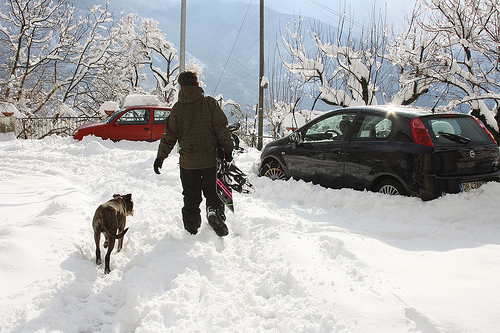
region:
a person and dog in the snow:
[33, 32, 373, 330]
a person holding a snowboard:
[129, 52, 281, 256]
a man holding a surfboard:
[122, 52, 259, 299]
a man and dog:
[51, 29, 301, 325]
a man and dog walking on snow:
[19, 35, 329, 327]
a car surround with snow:
[227, 62, 499, 263]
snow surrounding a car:
[211, 52, 499, 269]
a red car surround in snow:
[60, 50, 222, 177]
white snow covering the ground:
[224, 232, 404, 327]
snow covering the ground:
[266, 198, 467, 320]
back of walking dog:
[90, 196, 132, 261]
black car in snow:
[287, 105, 486, 217]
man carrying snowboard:
[161, 72, 243, 240]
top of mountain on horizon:
[280, 5, 318, 49]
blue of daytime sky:
[358, 3, 406, 28]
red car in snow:
[71, 97, 160, 159]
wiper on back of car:
[430, 121, 468, 154]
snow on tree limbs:
[330, 50, 423, 98]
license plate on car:
[450, 172, 490, 196]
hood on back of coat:
[171, 80, 213, 117]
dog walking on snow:
[93, 188, 133, 268]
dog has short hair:
[95, 191, 133, 267]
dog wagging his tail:
[93, 193, 133, 274]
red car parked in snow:
[71, 106, 173, 141]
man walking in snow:
[150, 71, 244, 240]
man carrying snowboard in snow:
[155, 71, 241, 236]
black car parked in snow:
[258, 107, 497, 193]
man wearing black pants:
[150, 74, 244, 237]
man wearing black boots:
[149, 71, 246, 236]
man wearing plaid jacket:
[148, 70, 243, 238]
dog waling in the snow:
[10, 194, 149, 264]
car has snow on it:
[71, 73, 164, 145]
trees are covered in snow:
[23, 16, 161, 124]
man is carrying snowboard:
[211, 145, 252, 222]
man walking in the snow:
[141, 65, 263, 290]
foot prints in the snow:
[315, 233, 460, 330]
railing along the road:
[21, 94, 164, 149]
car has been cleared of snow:
[323, 106, 496, 209]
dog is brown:
[90, 181, 122, 296]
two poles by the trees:
[171, 40, 303, 153]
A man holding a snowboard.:
[148, 63, 253, 251]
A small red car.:
[70, 102, 183, 146]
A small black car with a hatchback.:
[252, 97, 498, 202]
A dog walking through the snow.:
[73, 182, 148, 282]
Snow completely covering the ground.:
[1, 127, 496, 331]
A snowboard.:
[214, 123, 251, 213]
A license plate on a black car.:
[460, 180, 491, 195]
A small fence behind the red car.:
[5, 114, 108, 144]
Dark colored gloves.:
[146, 153, 239, 176]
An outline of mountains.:
[13, 1, 497, 119]